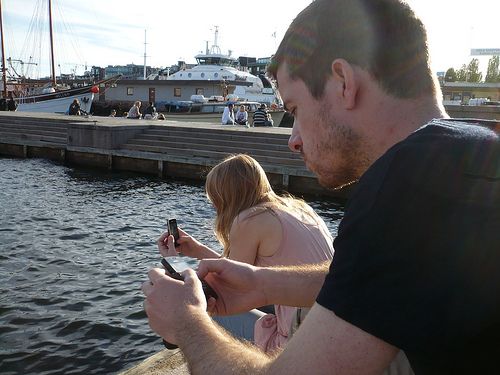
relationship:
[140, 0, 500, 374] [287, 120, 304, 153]
guy has nose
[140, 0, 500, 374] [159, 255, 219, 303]
guy using phone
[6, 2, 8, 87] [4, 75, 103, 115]
mast on boat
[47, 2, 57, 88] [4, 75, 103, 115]
mast on boat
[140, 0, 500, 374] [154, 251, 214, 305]
guy using phone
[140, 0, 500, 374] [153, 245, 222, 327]
guy using phone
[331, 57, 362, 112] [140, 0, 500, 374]
ear on guy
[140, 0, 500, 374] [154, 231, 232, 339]
guy using phone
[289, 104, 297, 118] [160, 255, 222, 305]
eye using cell phone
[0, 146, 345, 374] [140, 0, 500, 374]
water near guy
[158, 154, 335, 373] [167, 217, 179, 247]
lady using cell phone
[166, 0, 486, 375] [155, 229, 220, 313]
guy using phone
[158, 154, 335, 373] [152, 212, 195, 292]
lady using phones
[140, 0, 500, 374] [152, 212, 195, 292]
guy using phones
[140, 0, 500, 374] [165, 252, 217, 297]
guy on cellphone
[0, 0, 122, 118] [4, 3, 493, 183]
boat in marina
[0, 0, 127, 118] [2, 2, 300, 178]
boat in marina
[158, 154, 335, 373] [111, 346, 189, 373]
lady sitting on dock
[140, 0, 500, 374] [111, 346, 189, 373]
guy sitting on dock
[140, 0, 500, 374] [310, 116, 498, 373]
guy wearing t-shirt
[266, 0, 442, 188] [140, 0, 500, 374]
head on guy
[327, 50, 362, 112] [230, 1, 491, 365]
ear on person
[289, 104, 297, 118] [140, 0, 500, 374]
eye on guy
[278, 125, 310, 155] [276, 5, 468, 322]
nose on person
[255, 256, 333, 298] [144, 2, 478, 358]
arm on person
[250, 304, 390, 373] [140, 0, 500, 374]
arm on guy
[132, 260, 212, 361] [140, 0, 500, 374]
hand on guy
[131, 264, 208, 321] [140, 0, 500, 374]
fingers are on guy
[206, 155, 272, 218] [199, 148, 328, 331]
head on person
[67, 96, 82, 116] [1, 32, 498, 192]
man sitting on marina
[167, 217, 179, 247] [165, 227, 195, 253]
cell phone in hand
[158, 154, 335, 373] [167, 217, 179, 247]
lady holding cell phone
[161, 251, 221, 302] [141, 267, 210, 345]
cell phone in hand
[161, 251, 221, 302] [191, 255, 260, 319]
cell phone in man's hand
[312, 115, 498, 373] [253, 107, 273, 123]
sweater wearing sweater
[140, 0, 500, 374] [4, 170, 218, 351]
guy sitting by water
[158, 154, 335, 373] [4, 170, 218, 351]
lady sitting by water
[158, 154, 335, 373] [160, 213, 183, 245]
lady looking at phone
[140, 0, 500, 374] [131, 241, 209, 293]
guy using phone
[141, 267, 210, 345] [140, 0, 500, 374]
hand of guy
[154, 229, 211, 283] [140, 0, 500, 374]
hand of guy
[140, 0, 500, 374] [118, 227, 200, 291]
guy using phone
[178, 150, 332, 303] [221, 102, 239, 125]
head of lady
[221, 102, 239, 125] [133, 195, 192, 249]
lady using phone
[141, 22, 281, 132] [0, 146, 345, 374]
boat in water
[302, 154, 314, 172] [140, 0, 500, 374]
mouth of guy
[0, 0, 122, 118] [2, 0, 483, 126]
boat anchored in distance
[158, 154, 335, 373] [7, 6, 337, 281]
lady sitting in marina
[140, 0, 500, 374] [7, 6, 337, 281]
guy sitting in marina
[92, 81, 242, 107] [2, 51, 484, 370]
building standing in marina